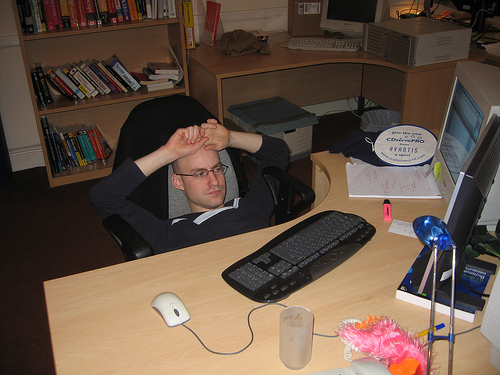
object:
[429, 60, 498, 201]
television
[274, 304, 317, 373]
glass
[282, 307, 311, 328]
drinking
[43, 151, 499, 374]
desk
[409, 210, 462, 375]
lamp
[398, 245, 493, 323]
texbook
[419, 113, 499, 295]
monitor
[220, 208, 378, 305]
keyboard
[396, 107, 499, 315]
computer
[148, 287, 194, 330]
mouse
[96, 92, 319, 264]
chair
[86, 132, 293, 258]
shirt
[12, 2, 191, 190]
book shelf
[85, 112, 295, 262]
man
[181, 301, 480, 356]
wire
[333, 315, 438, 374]
object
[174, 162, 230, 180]
glasses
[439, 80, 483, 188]
screen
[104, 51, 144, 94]
books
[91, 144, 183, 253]
arm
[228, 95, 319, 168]
file box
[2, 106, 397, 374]
floor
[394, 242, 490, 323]
book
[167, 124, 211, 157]
hands